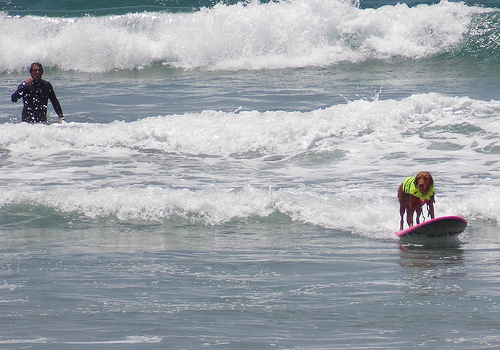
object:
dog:
[394, 171, 440, 230]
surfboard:
[393, 214, 472, 241]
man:
[10, 61, 68, 125]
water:
[299, 305, 499, 345]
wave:
[6, 6, 499, 74]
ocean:
[6, 8, 471, 77]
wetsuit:
[15, 80, 66, 120]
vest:
[400, 177, 432, 196]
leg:
[400, 204, 406, 228]